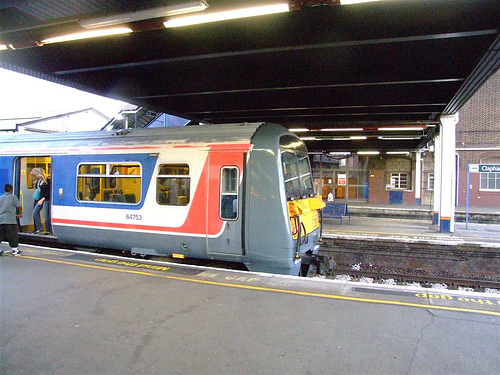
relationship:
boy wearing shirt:
[0, 183, 23, 256] [3, 191, 20, 225]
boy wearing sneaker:
[0, 185, 25, 257] [11, 247, 21, 256]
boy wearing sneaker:
[0, 185, 25, 257] [0, 246, 7, 256]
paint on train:
[0, 121, 327, 277] [0, 121, 333, 283]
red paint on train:
[203, 207, 221, 229] [1, 90, 348, 270]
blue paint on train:
[1, 154, 156, 210] [0, 121, 333, 283]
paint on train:
[2, 115, 327, 280] [2, 131, 315, 263]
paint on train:
[284, 193, 330, 237] [0, 121, 333, 283]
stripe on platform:
[1, 242, 497, 316] [2, 240, 499, 372]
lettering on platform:
[89, 252, 172, 273] [2, 240, 499, 372]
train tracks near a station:
[317, 232, 499, 287] [2, 0, 497, 225]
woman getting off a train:
[28, 165, 47, 235] [0, 121, 333, 283]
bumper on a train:
[283, 191, 338, 233] [0, 102, 343, 277]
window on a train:
[71, 159, 145, 211] [0, 121, 333, 283]